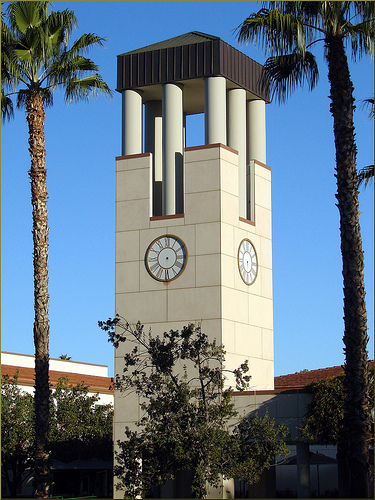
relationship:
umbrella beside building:
[305, 449, 335, 466] [7, 350, 369, 497]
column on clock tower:
[163, 84, 185, 215] [111, 31, 280, 498]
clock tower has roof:
[111, 31, 280, 498] [109, 27, 266, 92]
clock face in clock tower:
[145, 233, 187, 282] [111, 31, 280, 498]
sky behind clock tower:
[72, 0, 271, 64] [111, 31, 280, 498]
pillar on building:
[297, 445, 318, 498] [221, 366, 372, 445]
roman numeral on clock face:
[162, 234, 172, 246] [146, 236, 182, 282]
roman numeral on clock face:
[171, 258, 182, 268] [146, 236, 182, 282]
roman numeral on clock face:
[146, 256, 158, 265] [146, 236, 182, 282]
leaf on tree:
[235, 19, 335, 154] [245, 0, 362, 203]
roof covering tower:
[89, 8, 281, 125] [101, 16, 283, 449]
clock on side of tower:
[143, 229, 205, 288] [101, 16, 283, 449]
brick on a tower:
[164, 282, 223, 318] [101, 16, 283, 449]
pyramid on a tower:
[106, 25, 279, 106] [112, 29, 284, 389]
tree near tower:
[5, 0, 123, 491] [109, 11, 276, 445]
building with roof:
[100, 35, 297, 442] [98, 12, 302, 121]